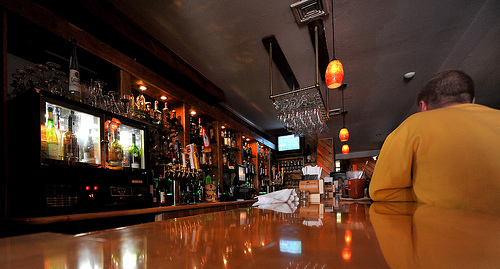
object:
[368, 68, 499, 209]
man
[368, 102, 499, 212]
shirt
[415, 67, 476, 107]
hair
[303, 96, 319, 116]
glasses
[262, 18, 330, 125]
rack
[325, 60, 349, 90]
light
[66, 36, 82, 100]
bottle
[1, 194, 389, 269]
bar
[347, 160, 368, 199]
drink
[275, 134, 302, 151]
tv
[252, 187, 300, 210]
towel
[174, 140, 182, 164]
tap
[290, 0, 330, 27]
vent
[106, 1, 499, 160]
ceiling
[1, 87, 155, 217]
refrigerator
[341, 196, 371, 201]
napkin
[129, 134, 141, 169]
bottle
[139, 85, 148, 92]
light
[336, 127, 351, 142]
light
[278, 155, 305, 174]
shelf